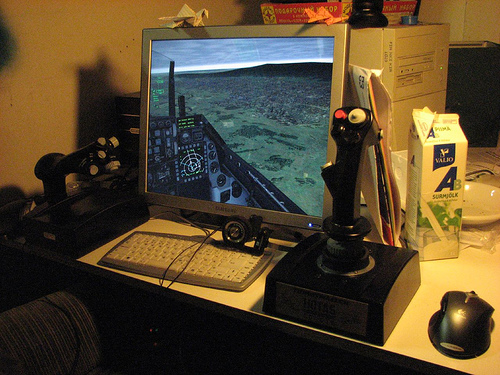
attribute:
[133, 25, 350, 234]
computer monitor — silver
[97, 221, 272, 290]
keyboard — computer, in the picture, white, wired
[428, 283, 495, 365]
mouse — black, Logitech, computer, wireless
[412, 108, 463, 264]
milk packet — white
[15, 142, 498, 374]
table — white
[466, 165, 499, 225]
plate — white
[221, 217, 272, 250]
webcam — black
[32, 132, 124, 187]
joystick — black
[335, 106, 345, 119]
button — red, white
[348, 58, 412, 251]
paper — folded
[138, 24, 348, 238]
2. screen — in the picture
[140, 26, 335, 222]
2. screen — in the picture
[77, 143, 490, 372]
2. table — in the picture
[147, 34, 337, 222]
2. cartoons — in the picture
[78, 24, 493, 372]
2. desk — in the picture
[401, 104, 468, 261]
2. container — in the picture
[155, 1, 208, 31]
2. swan — in the picture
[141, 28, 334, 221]
2. game — in the picture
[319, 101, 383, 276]
2. handle — in the picture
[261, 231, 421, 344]
2. base — in the picture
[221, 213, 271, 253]
2. headphones — in the picture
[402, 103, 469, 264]
2. carton — in the picture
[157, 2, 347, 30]
2. designs — in the picture